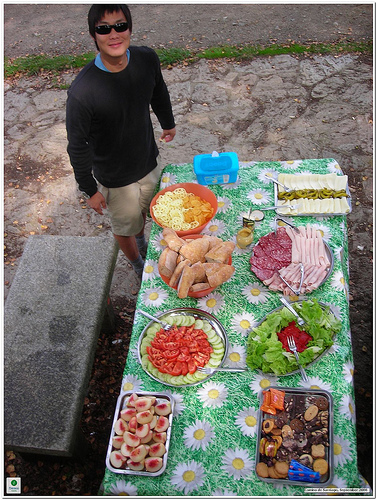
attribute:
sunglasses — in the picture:
[90, 21, 130, 35]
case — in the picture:
[189, 146, 243, 184]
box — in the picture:
[191, 150, 238, 185]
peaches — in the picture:
[111, 387, 167, 472]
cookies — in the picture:
[85, 393, 205, 479]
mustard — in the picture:
[233, 218, 272, 248]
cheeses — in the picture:
[275, 198, 349, 213]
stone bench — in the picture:
[6, 232, 118, 459]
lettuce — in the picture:
[247, 299, 340, 375]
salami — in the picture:
[241, 233, 298, 285]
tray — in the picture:
[319, 244, 338, 272]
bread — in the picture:
[165, 234, 229, 288]